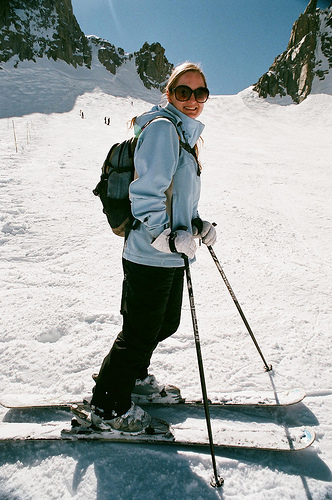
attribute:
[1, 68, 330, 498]
snow — white, on ground, thick, reflecting light, a lot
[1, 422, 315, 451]
ski — snow covered, white, being worn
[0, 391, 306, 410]
ski — snow covered, white, being worn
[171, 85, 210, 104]
shades — black, big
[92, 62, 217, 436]
woman — skiing, wearing blue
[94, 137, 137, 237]
backpack — blue, black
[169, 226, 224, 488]
ski pole — black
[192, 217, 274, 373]
ski pole — black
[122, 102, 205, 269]
jacket — blue, hooded, light blue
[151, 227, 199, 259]
glove — white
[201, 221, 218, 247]
glove — white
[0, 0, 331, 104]
mountains — snowy, in background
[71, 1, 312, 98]
sky — blue, clear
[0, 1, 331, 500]
landscape — snowy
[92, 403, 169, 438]
snow boot — snow covered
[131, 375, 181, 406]
snow boot — snow covered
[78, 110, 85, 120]
skiers — in distance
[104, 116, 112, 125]
skiers — in distance